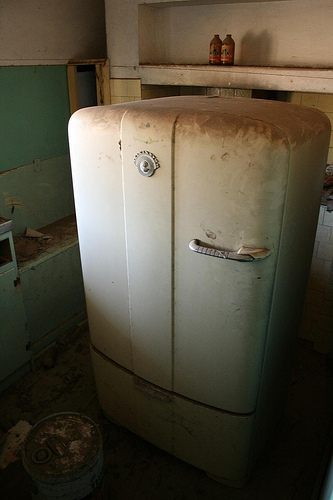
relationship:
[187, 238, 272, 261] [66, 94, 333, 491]
handle on chest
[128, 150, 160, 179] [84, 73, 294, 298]
logo on fridge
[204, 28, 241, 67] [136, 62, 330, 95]
botttles sitting on shelf